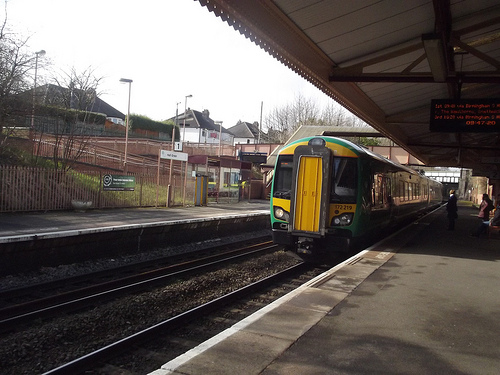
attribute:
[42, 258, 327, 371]
tracks — occupied 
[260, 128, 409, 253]
woman — wearing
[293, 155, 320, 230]
door — yellow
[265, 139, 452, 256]
train — moving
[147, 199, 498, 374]
platform — cement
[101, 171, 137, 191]
banner — green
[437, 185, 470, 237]
man — wearing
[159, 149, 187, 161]
posting — white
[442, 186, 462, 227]
man — wearing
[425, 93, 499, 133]
sign — electric